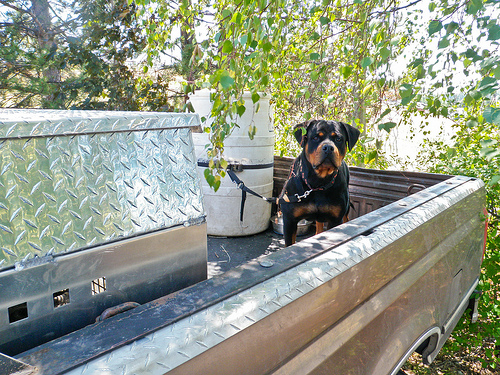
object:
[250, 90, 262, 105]
leaf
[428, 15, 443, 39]
leaf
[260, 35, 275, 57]
leaf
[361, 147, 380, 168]
leaf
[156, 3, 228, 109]
tree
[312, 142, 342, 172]
nose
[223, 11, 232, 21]
leaves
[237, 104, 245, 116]
leaves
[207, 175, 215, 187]
leaves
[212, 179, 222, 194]
leaves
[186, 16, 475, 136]
leaves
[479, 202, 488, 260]
rear taillights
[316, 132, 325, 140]
spot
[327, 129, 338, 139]
spot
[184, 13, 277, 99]
leaves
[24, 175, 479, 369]
metal strip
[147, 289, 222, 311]
rusted spots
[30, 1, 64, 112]
tree trunk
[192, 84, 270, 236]
white barrel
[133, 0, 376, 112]
leaves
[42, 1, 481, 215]
tree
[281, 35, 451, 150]
leaves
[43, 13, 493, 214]
trees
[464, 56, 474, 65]
leaf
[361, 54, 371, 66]
leaf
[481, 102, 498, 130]
leaf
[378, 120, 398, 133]
leaf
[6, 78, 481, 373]
truck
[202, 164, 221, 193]
leaves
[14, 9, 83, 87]
trees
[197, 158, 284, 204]
leash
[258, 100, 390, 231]
dog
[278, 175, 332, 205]
collar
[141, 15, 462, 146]
branch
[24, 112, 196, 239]
pattern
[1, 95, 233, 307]
tool box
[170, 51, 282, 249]
barrel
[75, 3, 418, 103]
branches